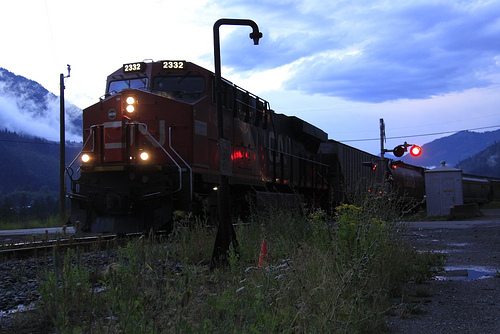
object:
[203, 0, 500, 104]
cloud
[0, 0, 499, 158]
sky